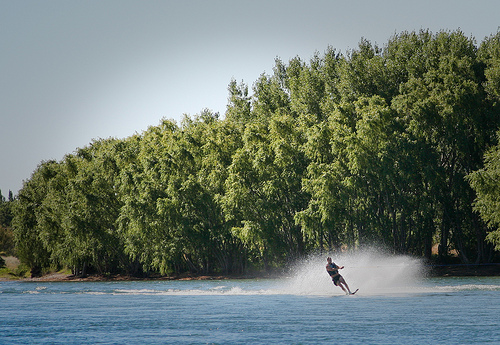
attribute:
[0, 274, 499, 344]
water — lake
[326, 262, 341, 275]
vest — life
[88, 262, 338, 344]
water — white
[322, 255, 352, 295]
person — waterskiing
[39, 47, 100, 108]
sky — grey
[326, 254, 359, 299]
man — skating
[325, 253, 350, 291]
person — pictured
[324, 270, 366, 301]
ski — part, up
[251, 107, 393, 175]
leaves — green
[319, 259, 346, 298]
shorts — black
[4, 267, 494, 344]
lake — big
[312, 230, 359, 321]
man — pictured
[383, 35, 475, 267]
tree — pictured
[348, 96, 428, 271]
tree — pictured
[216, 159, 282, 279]
tree — pictured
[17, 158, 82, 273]
tree — pictured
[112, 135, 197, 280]
tree — pictured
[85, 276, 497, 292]
waves — white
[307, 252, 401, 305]
waterskiing — pictured